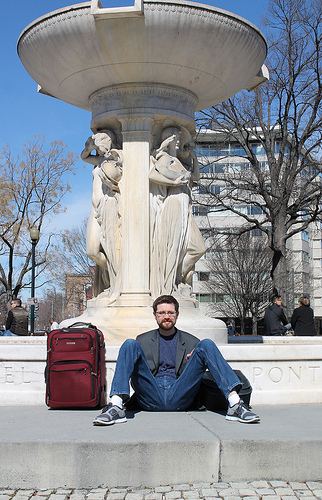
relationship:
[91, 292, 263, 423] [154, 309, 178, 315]
man wearing glasses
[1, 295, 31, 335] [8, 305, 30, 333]
man wearing vest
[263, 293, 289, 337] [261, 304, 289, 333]
man wearing suit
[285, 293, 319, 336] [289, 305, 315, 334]
woman wearing coat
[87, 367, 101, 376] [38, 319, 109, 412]
zipper on luggage bag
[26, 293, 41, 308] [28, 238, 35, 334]
sign on pole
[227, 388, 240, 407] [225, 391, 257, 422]
sock on left foot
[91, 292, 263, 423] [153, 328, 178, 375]
man wearing shirt